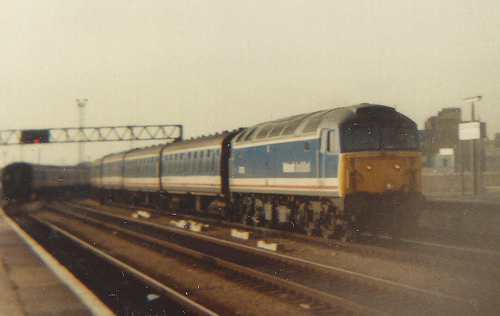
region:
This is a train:
[40, 97, 452, 247]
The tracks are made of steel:
[168, 209, 354, 302]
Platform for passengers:
[3, 223, 68, 313]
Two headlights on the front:
[358, 152, 414, 176]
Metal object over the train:
[1, 115, 192, 141]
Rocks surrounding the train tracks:
[110, 202, 318, 314]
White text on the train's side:
[272, 152, 327, 179]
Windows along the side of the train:
[104, 153, 317, 181]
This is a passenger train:
[84, 110, 365, 192]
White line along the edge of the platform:
[3, 197, 89, 314]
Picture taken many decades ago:
[10, 8, 491, 305]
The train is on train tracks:
[87, 78, 444, 252]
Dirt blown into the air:
[341, 120, 481, 277]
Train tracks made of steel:
[110, 233, 386, 314]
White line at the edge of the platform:
[8, 207, 103, 314]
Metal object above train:
[7, 118, 187, 144]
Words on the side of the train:
[267, 153, 319, 175]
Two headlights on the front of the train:
[359, 154, 408, 178]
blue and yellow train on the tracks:
[85, 94, 422, 234]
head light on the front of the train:
[362, 160, 374, 175]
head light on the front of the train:
[378, 179, 395, 193]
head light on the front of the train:
[391, 160, 401, 174]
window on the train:
[337, 118, 379, 155]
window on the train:
[380, 122, 422, 151]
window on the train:
[298, 110, 323, 135]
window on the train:
[281, 118, 301, 137]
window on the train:
[262, 118, 287, 138]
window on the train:
[257, 121, 274, 138]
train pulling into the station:
[83, 123, 409, 220]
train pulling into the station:
[8, 147, 54, 199]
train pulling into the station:
[182, 112, 431, 222]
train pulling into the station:
[8, 145, 64, 205]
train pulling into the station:
[231, 102, 435, 244]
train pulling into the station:
[152, 100, 435, 210]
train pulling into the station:
[112, 88, 432, 210]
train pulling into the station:
[238, 106, 434, 249]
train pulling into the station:
[3, 142, 57, 198]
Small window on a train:
[207, 146, 222, 161]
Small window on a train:
[200, 145, 210, 162]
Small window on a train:
[190, 148, 207, 154]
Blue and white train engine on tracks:
[229, 110, 418, 241]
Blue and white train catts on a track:
[160, 137, 229, 223]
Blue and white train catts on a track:
[121, 136, 161, 216]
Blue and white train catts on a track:
[100, 148, 132, 204]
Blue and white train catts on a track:
[15, 156, 86, 200]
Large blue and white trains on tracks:
[68, 90, 390, 230]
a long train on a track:
[82, 100, 427, 242]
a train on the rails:
[80, 102, 422, 245]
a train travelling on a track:
[85, 106, 431, 247]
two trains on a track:
[8, 103, 418, 246]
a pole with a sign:
[455, 93, 493, 196]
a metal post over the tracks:
[0, 113, 197, 153]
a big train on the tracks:
[93, 103, 431, 242]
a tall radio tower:
[72, 91, 93, 163]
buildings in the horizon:
[420, 101, 497, 176]